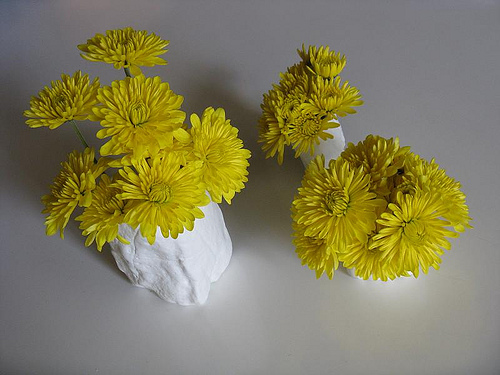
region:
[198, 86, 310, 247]
A shadow on the table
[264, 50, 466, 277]
Flowers on the table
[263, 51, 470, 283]
The flowers are yellow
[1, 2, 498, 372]
Yellow flowers on the table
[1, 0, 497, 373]
A table beneath the flowers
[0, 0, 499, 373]
The table is white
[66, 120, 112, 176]
The stem of the flower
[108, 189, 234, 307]
A flower holder for the flowers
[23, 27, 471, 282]
A bunch of yellow flowers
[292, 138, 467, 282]
The flowers are blooming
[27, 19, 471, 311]
yellow flowers are in vases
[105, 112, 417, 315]
the vases appear to be made out of clay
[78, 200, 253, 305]
the clay is white in color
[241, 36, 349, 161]
the bunch of flowers is the smallest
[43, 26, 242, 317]
this bunch of flowers is the biggest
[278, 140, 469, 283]
this bunch of flowers has more than the smallest bunch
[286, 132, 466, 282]
this bunch of flowers has less than the biggest bunch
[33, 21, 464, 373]
the surface the vases are on is white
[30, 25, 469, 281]
the flowers have yellow petals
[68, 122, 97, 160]
the flowers stem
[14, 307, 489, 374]
a white table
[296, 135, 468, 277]
a bouquet of yellow flowers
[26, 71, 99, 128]
a yellow flower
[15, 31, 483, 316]
a bunch of yellow flowers on a table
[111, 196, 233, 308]
a white vase the flowers are in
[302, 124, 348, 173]
another white vase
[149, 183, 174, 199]
the inner part of the flower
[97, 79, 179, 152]
a large yellow flower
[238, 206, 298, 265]
a shadow on the table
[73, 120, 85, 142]
a stem of the flower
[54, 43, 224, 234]
the flowers are yellow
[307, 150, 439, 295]
the flowers are yellow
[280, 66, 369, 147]
the flowers are yellow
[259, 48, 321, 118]
the flowers are yellow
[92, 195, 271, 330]
the sponge is white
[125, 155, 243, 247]
yellow petals on plant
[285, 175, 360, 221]
yellow petals on plant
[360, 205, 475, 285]
yellow petals on plant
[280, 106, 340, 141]
yellow petals on plant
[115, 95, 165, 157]
yellow petals on plant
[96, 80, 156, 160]
yellow petals on plant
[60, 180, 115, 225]
yellow petals on plant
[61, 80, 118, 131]
yellow petals on plant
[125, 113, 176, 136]
yellow petals on plant